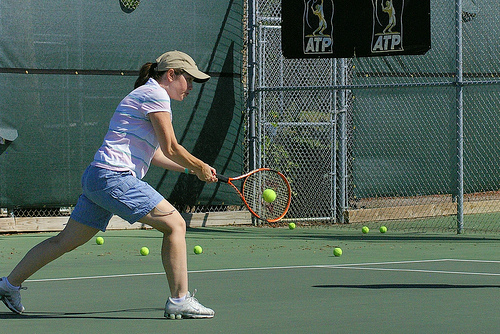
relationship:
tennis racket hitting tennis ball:
[213, 166, 293, 223] [264, 188, 276, 202]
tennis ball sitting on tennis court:
[334, 247, 344, 257] [0, 211, 499, 333]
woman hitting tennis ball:
[0, 50, 219, 320] [264, 188, 276, 202]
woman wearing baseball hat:
[0, 50, 219, 320] [153, 50, 212, 85]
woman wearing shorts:
[0, 50, 219, 320] [69, 164, 166, 233]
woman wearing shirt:
[0, 50, 219, 320] [90, 76, 173, 180]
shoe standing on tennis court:
[164, 287, 215, 319] [0, 211, 499, 333]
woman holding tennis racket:
[0, 50, 219, 320] [213, 166, 293, 223]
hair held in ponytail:
[134, 61, 185, 89] [133, 62, 158, 90]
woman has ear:
[0, 50, 219, 320] [166, 68, 175, 82]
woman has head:
[0, 50, 219, 320] [155, 49, 198, 103]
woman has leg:
[0, 50, 219, 320] [103, 174, 188, 299]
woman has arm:
[0, 50, 219, 320] [147, 104, 204, 171]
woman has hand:
[0, 50, 219, 320] [195, 162, 217, 182]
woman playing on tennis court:
[0, 50, 219, 320] [0, 211, 499, 333]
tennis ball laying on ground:
[334, 247, 344, 257] [0, 191, 500, 333]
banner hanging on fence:
[280, 0, 432, 61] [247, 0, 499, 235]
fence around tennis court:
[247, 0, 499, 235] [0, 211, 499, 333]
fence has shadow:
[247, 0, 499, 235] [142, 0, 255, 233]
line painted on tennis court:
[23, 257, 451, 281] [0, 211, 499, 333]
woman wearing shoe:
[0, 50, 219, 320] [1, 276, 25, 314]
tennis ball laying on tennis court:
[334, 247, 344, 257] [0, 211, 499, 333]